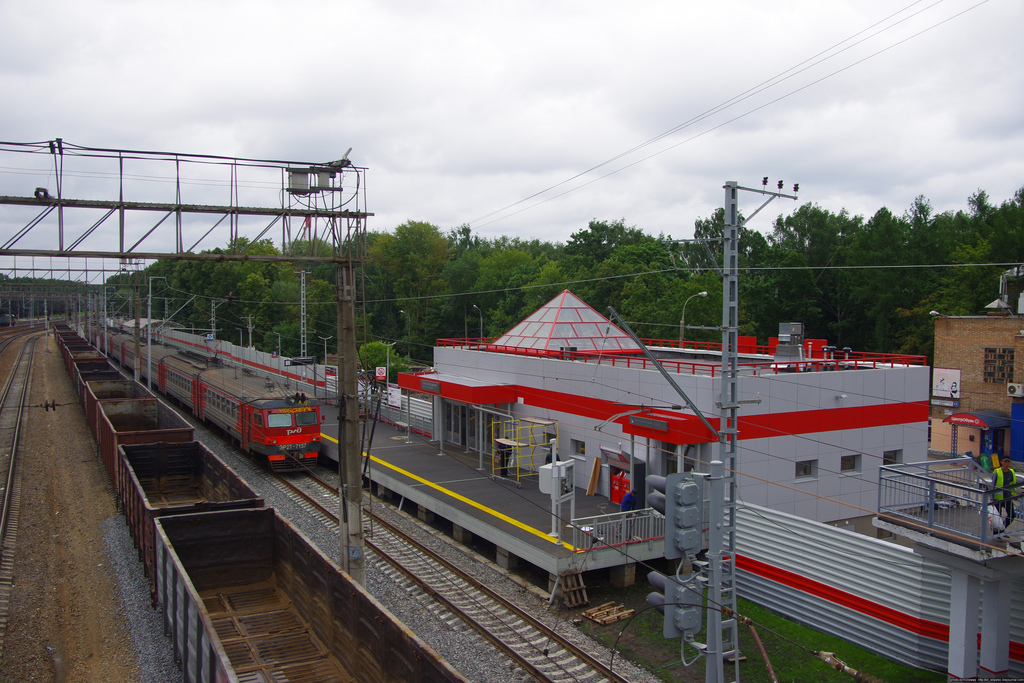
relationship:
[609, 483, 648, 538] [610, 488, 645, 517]
person in blue jacket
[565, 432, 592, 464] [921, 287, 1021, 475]
window on building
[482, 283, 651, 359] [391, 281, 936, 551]
pyramid roof on building